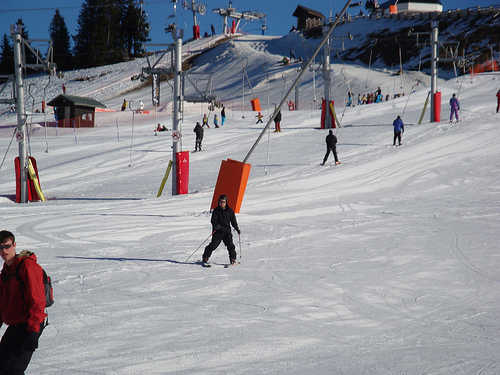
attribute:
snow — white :
[3, 16, 498, 372]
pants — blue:
[216, 113, 226, 128]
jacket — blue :
[390, 117, 404, 129]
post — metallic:
[149, 27, 204, 163]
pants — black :
[3, 319, 48, 369]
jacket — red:
[1, 247, 51, 341]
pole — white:
[239, 8, 349, 160]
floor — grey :
[12, 85, 499, 372]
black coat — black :
[205, 205, 242, 239]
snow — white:
[343, 192, 403, 285]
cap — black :
[214, 193, 228, 201]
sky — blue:
[8, 4, 498, 79]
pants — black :
[201, 227, 238, 261]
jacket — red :
[5, 250, 59, 343]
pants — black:
[200, 229, 238, 265]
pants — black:
[0, 323, 47, 373]